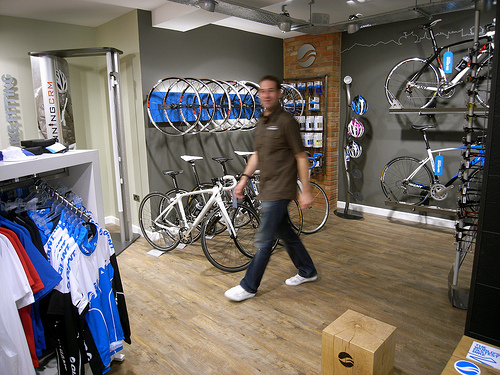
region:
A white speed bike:
[137, 170, 262, 272]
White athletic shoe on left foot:
[222, 283, 254, 303]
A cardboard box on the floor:
[320, 308, 395, 374]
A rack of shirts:
[0, 173, 132, 372]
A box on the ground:
[441, 334, 498, 374]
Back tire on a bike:
[380, 155, 434, 207]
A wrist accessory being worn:
[239, 172, 250, 180]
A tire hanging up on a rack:
[147, 76, 200, 133]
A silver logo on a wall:
[296, 44, 316, 67]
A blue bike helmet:
[350, 95, 368, 114]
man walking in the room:
[212, 81, 352, 312]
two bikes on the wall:
[364, 15, 489, 227]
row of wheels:
[134, 61, 319, 140]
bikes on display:
[144, 143, 333, 284]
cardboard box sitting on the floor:
[312, 307, 407, 373]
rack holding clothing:
[25, 189, 151, 371]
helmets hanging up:
[339, 70, 368, 213]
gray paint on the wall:
[137, 17, 307, 246]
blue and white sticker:
[455, 354, 478, 374]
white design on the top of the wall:
[347, 17, 493, 52]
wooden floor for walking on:
[133, 302, 315, 371]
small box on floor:
[325, 314, 392, 370]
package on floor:
[442, 332, 498, 374]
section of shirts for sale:
[3, 188, 130, 363]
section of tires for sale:
[150, 77, 243, 133]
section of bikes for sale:
[150, 151, 241, 266]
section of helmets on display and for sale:
[346, 96, 366, 161]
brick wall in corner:
[325, 35, 335, 203]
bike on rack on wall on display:
[389, 18, 484, 108]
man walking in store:
[231, 73, 322, 295]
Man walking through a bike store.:
[224, 76, 316, 303]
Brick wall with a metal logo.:
[282, 32, 337, 212]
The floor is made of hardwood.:
[101, 218, 466, 374]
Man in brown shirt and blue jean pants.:
[224, 75, 316, 301]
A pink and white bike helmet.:
[348, 118, 364, 138]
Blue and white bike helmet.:
[348, 94, 366, 114]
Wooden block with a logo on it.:
[322, 308, 397, 373]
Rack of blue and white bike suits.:
[45, 188, 130, 372]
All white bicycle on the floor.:
[138, 169, 262, 271]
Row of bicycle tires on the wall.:
[147, 77, 304, 134]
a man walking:
[223, 80, 328, 297]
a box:
[321, 308, 404, 365]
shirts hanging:
[62, 246, 144, 369]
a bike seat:
[156, 165, 182, 177]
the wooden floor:
[150, 295, 226, 357]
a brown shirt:
[251, 127, 291, 203]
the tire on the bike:
[384, 153, 404, 167]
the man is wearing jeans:
[255, 205, 277, 239]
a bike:
[142, 168, 237, 269]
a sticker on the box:
[452, 360, 496, 373]